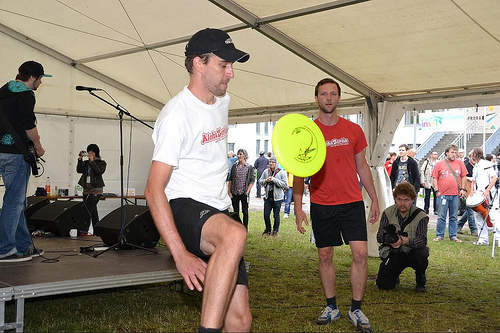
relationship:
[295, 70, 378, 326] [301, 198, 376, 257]
man in shorts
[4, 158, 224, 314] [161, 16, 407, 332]
stage behind men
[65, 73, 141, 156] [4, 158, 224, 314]
microphone on stage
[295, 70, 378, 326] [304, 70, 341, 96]
man has hair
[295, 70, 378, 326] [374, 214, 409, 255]
man holding camera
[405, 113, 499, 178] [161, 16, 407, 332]
stairs behind men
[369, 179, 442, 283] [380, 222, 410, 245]
person taking picture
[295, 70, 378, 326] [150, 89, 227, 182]
man in white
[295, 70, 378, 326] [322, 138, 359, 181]
man in red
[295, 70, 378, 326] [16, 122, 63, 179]
man playing guitar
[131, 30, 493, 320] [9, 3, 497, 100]
people under tent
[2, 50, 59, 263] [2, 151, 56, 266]
man wearing jeans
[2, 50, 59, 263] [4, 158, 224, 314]
man on stage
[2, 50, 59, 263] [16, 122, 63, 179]
guy playing instrument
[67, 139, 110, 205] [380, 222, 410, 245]
woman taking picture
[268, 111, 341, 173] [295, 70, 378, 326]
frisbee by man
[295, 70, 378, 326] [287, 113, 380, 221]
man in tshirt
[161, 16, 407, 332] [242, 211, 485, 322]
men in grass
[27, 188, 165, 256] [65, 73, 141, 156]
speakers for microphone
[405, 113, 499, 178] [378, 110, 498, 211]
stairs to building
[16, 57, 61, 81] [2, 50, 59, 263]
hat on guy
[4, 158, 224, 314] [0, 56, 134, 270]
stage for band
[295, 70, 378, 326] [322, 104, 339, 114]
man has beard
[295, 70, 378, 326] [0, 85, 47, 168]
man in black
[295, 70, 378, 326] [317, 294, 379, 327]
man wearing shoes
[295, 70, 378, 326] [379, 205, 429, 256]
man wearing vest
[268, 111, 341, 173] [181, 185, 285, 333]
frisbee between legs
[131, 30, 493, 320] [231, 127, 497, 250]
people in crowd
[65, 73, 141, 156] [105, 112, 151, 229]
microphone with stand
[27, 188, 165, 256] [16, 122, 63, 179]
speakers for guitar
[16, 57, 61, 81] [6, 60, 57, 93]
hat on head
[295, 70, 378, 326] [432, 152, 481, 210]
man in orange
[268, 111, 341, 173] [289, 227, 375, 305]
frisbee above ground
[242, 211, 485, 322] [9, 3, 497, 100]
grass inside tent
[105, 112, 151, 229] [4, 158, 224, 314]
stand on stage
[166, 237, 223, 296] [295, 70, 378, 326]
hand of man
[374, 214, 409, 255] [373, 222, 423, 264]
camera in hands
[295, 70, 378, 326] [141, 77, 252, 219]
man wearing shirt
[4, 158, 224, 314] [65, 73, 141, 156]
stage under microphone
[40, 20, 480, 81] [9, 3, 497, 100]
roof of tent